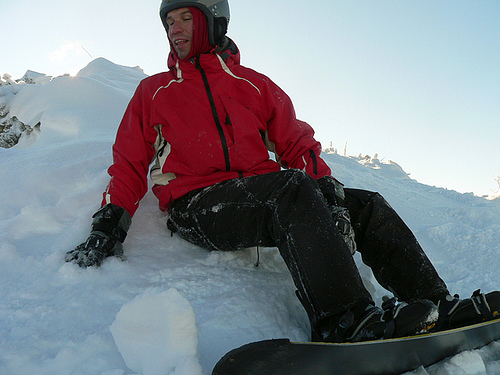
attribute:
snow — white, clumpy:
[59, 122, 104, 155]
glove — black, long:
[82, 203, 134, 275]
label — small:
[101, 188, 113, 203]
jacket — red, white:
[116, 53, 316, 178]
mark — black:
[218, 100, 253, 166]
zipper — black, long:
[190, 62, 233, 167]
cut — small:
[142, 130, 181, 199]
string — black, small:
[254, 240, 266, 270]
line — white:
[209, 54, 264, 101]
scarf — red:
[187, 11, 218, 55]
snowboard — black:
[221, 330, 476, 369]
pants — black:
[204, 171, 427, 306]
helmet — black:
[161, 2, 233, 46]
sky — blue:
[281, 15, 478, 94]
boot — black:
[362, 299, 440, 335]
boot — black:
[454, 289, 496, 317]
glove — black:
[320, 173, 361, 250]